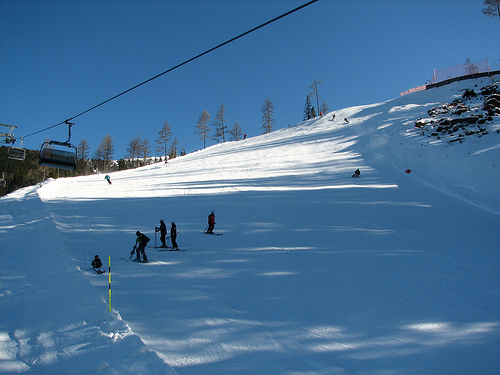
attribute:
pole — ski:
[148, 222, 163, 247]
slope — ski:
[98, 100, 431, 368]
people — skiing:
[125, 204, 222, 261]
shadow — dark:
[287, 125, 353, 156]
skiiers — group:
[84, 166, 361, 273]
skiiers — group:
[239, 109, 360, 139]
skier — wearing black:
[199, 208, 234, 240]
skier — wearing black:
[165, 221, 188, 252]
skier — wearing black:
[152, 214, 175, 251]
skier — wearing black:
[122, 226, 159, 261]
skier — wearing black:
[89, 251, 112, 278]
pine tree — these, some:
[196, 104, 214, 151]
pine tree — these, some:
[209, 103, 229, 143]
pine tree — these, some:
[227, 120, 242, 147]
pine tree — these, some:
[252, 93, 277, 131]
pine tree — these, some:
[154, 117, 181, 177]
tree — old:
[259, 98, 279, 135]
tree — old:
[213, 100, 235, 140]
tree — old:
[195, 108, 213, 146]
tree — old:
[149, 118, 177, 158]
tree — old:
[93, 130, 118, 169]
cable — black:
[34, 1, 308, 126]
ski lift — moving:
[35, 126, 83, 173]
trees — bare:
[386, 45, 463, 150]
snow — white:
[2, 67, 498, 368]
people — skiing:
[202, 209, 220, 240]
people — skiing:
[167, 220, 184, 251]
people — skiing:
[147, 218, 170, 259]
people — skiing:
[129, 233, 154, 269]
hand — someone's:
[153, 223, 163, 233]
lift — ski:
[7, 2, 340, 165]